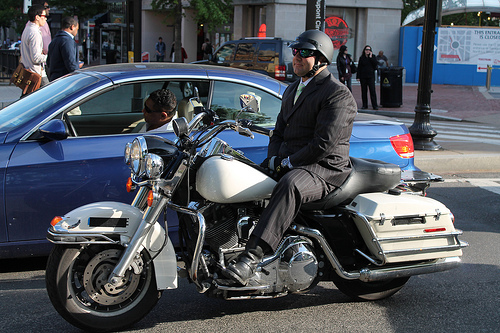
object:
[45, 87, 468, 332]
motorcycle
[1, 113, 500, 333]
road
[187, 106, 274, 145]
handlebars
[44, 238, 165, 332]
front tire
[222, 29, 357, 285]
man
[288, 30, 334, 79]
helmet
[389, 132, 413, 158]
brake light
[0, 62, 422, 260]
car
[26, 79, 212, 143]
window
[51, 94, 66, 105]
rearview mirror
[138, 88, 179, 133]
man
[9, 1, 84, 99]
people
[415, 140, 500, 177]
sidewalk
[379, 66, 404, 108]
recycling bin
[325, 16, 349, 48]
neon sign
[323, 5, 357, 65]
window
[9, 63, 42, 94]
satchel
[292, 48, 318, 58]
sunglasses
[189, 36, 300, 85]
suv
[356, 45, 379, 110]
woman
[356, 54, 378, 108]
black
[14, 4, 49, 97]
man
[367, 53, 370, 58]
cellphone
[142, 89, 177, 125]
head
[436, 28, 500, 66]
map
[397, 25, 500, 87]
wall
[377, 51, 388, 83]
man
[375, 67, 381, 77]
bench